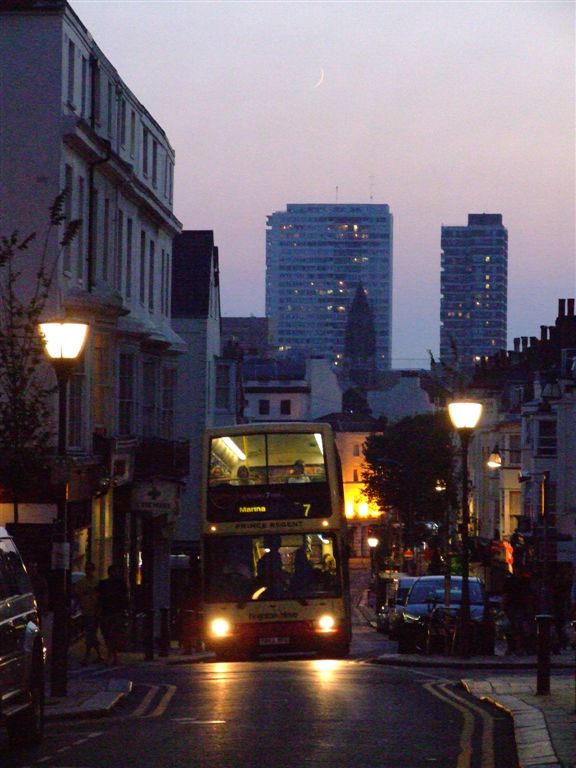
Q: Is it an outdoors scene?
A: Yes, it is outdoors.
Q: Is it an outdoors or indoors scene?
A: It is outdoors.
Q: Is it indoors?
A: No, it is outdoors.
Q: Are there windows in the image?
A: Yes, there is a window.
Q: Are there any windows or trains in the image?
A: Yes, there is a window.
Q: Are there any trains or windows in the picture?
A: Yes, there is a window.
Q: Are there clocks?
A: No, there are no clocks.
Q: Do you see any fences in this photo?
A: No, there are no fences.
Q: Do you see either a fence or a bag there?
A: No, there are no fences or bags.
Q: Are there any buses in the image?
A: Yes, there is a bus.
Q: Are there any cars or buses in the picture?
A: Yes, there is a bus.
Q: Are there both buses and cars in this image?
A: Yes, there are both a bus and a car.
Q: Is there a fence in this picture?
A: No, there are no fences.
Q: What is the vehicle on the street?
A: The vehicle is a bus.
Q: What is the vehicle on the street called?
A: The vehicle is a bus.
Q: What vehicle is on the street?
A: The vehicle is a bus.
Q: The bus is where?
A: The bus is on the street.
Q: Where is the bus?
A: The bus is on the street.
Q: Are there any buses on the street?
A: Yes, there is a bus on the street.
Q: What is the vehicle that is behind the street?
A: The vehicle is a bus.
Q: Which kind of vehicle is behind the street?
A: The vehicle is a bus.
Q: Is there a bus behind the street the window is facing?
A: Yes, there is a bus behind the street.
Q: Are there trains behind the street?
A: No, there is a bus behind the street.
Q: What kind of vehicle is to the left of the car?
A: The vehicle is a bus.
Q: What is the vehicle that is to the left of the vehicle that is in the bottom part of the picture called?
A: The vehicle is a bus.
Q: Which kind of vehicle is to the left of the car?
A: The vehicle is a bus.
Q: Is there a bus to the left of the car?
A: Yes, there is a bus to the left of the car.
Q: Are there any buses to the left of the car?
A: Yes, there is a bus to the left of the car.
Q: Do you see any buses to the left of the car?
A: Yes, there is a bus to the left of the car.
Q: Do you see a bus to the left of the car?
A: Yes, there is a bus to the left of the car.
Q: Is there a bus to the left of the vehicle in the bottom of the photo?
A: Yes, there is a bus to the left of the car.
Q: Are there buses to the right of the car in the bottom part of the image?
A: No, the bus is to the left of the car.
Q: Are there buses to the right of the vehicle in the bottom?
A: No, the bus is to the left of the car.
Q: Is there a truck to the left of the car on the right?
A: No, there is a bus to the left of the car.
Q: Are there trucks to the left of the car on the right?
A: No, there is a bus to the left of the car.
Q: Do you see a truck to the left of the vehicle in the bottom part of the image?
A: No, there is a bus to the left of the car.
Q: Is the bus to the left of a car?
A: Yes, the bus is to the left of a car.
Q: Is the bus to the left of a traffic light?
A: No, the bus is to the left of a car.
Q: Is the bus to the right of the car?
A: No, the bus is to the left of the car.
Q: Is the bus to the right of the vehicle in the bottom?
A: No, the bus is to the left of the car.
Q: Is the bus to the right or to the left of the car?
A: The bus is to the left of the car.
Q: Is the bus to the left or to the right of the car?
A: The bus is to the left of the car.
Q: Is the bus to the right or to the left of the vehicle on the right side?
A: The bus is to the left of the car.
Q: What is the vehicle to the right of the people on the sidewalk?
A: The vehicle is a bus.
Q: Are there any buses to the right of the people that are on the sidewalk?
A: Yes, there is a bus to the right of the people.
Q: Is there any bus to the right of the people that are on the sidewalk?
A: Yes, there is a bus to the right of the people.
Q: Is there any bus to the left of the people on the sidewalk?
A: No, the bus is to the right of the people.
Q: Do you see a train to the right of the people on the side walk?
A: No, there is a bus to the right of the people.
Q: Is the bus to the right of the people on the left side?
A: Yes, the bus is to the right of the people.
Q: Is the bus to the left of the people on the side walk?
A: No, the bus is to the right of the people.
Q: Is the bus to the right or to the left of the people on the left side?
A: The bus is to the right of the people.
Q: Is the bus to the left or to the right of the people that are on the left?
A: The bus is to the right of the people.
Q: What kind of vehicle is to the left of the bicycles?
A: The vehicle is a bus.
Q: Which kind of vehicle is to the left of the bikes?
A: The vehicle is a bus.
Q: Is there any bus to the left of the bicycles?
A: Yes, there is a bus to the left of the bicycles.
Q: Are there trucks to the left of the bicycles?
A: No, there is a bus to the left of the bicycles.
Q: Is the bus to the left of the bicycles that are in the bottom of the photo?
A: Yes, the bus is to the left of the bicycles.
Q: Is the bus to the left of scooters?
A: No, the bus is to the left of the bicycles.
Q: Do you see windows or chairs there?
A: Yes, there is a window.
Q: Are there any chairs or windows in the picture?
A: Yes, there is a window.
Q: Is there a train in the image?
A: No, there are no trains.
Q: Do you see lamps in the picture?
A: Yes, there is a lamp.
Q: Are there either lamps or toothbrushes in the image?
A: Yes, there is a lamp.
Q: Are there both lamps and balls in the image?
A: No, there is a lamp but no balls.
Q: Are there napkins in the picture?
A: No, there are no napkins.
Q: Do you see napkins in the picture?
A: No, there are no napkins.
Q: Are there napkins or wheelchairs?
A: No, there are no napkins or wheelchairs.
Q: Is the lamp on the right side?
A: Yes, the lamp is on the right of the image.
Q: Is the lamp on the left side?
A: No, the lamp is on the right of the image.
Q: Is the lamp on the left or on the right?
A: The lamp is on the right of the image.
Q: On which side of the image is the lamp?
A: The lamp is on the right of the image.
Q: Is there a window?
A: Yes, there is a window.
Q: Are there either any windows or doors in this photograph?
A: Yes, there is a window.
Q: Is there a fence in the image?
A: No, there are no fences.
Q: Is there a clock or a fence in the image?
A: No, there are no fences or clocks.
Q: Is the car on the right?
A: Yes, the car is on the right of the image.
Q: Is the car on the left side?
A: No, the car is on the right of the image.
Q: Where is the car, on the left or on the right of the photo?
A: The car is on the right of the image.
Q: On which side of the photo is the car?
A: The car is on the right of the image.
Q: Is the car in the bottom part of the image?
A: Yes, the car is in the bottom of the image.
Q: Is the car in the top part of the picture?
A: No, the car is in the bottom of the image.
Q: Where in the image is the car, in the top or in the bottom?
A: The car is in the bottom of the image.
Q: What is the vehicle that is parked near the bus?
A: The vehicle is a car.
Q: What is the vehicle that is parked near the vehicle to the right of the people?
A: The vehicle is a car.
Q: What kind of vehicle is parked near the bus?
A: The vehicle is a car.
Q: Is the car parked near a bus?
A: Yes, the car is parked near a bus.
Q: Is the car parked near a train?
A: No, the car is parked near a bus.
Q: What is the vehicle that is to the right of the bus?
A: The vehicle is a car.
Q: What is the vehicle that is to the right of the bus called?
A: The vehicle is a car.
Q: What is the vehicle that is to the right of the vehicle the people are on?
A: The vehicle is a car.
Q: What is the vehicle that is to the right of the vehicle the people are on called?
A: The vehicle is a car.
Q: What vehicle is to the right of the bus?
A: The vehicle is a car.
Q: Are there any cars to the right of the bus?
A: Yes, there is a car to the right of the bus.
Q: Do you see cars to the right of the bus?
A: Yes, there is a car to the right of the bus.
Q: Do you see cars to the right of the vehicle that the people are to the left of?
A: Yes, there is a car to the right of the bus.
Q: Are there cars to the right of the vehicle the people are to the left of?
A: Yes, there is a car to the right of the bus.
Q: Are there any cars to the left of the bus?
A: No, the car is to the right of the bus.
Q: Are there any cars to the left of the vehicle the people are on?
A: No, the car is to the right of the bus.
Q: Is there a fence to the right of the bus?
A: No, there is a car to the right of the bus.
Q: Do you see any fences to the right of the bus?
A: No, there is a car to the right of the bus.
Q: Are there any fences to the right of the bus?
A: No, there is a car to the right of the bus.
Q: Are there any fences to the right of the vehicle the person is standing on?
A: No, there is a car to the right of the bus.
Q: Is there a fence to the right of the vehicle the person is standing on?
A: No, there is a car to the right of the bus.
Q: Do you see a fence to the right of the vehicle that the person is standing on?
A: No, there is a car to the right of the bus.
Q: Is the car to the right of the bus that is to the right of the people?
A: Yes, the car is to the right of the bus.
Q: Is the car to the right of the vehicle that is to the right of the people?
A: Yes, the car is to the right of the bus.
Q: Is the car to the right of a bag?
A: No, the car is to the right of the bus.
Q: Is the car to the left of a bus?
A: No, the car is to the right of a bus.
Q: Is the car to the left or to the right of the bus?
A: The car is to the right of the bus.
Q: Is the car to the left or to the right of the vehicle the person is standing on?
A: The car is to the right of the bus.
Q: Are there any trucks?
A: No, there are no trucks.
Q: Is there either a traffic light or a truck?
A: No, there are no trucks or traffic lights.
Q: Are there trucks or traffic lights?
A: No, there are no trucks or traffic lights.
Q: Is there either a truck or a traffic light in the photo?
A: No, there are no trucks or traffic lights.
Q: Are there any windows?
A: Yes, there is a window.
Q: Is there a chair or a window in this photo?
A: Yes, there is a window.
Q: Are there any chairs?
A: No, there are no chairs.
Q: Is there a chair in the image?
A: No, there are no chairs.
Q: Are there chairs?
A: No, there are no chairs.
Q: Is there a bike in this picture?
A: Yes, there are bikes.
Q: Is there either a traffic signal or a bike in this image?
A: Yes, there are bikes.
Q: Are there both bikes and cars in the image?
A: Yes, there are both bikes and a car.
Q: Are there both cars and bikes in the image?
A: Yes, there are both bikes and a car.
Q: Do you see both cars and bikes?
A: Yes, there are both bikes and a car.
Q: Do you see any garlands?
A: No, there are no garlands.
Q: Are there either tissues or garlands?
A: No, there are no garlands or tissues.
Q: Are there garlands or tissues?
A: No, there are no garlands or tissues.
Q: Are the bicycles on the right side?
A: Yes, the bicycles are on the right of the image.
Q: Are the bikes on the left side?
A: No, the bikes are on the right of the image.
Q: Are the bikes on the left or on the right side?
A: The bikes are on the right of the image.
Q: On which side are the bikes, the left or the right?
A: The bikes are on the right of the image.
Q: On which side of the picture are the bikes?
A: The bikes are on the right of the image.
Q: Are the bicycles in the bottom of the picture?
A: Yes, the bicycles are in the bottom of the image.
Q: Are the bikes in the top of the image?
A: No, the bikes are in the bottom of the image.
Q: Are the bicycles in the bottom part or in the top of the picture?
A: The bicycles are in the bottom of the image.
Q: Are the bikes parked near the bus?
A: Yes, the bikes are parked near the bus.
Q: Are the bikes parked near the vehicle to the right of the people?
A: Yes, the bikes are parked near the bus.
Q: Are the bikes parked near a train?
A: No, the bikes are parked near the bus.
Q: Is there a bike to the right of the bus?
A: Yes, there are bikes to the right of the bus.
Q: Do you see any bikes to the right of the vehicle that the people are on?
A: Yes, there are bikes to the right of the bus.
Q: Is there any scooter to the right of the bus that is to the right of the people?
A: No, there are bikes to the right of the bus.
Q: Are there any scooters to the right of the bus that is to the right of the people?
A: No, there are bikes to the right of the bus.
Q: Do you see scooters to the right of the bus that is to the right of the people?
A: No, there are bikes to the right of the bus.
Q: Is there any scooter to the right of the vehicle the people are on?
A: No, there are bikes to the right of the bus.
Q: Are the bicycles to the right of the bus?
A: Yes, the bicycles are to the right of the bus.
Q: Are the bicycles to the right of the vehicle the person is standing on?
A: Yes, the bicycles are to the right of the bus.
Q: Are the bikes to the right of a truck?
A: No, the bikes are to the right of the bus.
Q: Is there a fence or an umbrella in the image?
A: No, there are no fences or umbrellas.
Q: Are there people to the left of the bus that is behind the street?
A: Yes, there are people to the left of the bus.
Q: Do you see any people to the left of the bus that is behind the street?
A: Yes, there are people to the left of the bus.